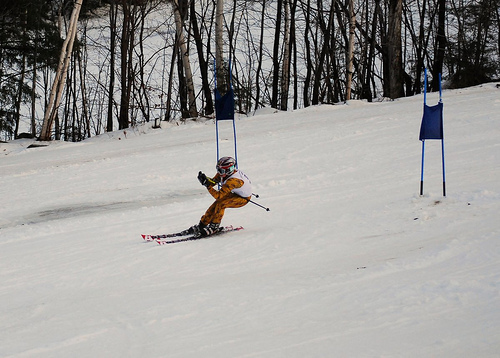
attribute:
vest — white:
[220, 169, 255, 198]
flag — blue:
[419, 68, 449, 201]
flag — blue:
[211, 57, 239, 163]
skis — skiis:
[141, 223, 247, 247]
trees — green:
[3, 1, 496, 146]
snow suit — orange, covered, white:
[197, 171, 250, 234]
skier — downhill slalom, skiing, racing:
[135, 153, 275, 249]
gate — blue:
[208, 67, 451, 203]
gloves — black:
[198, 171, 209, 187]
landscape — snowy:
[5, 2, 496, 357]